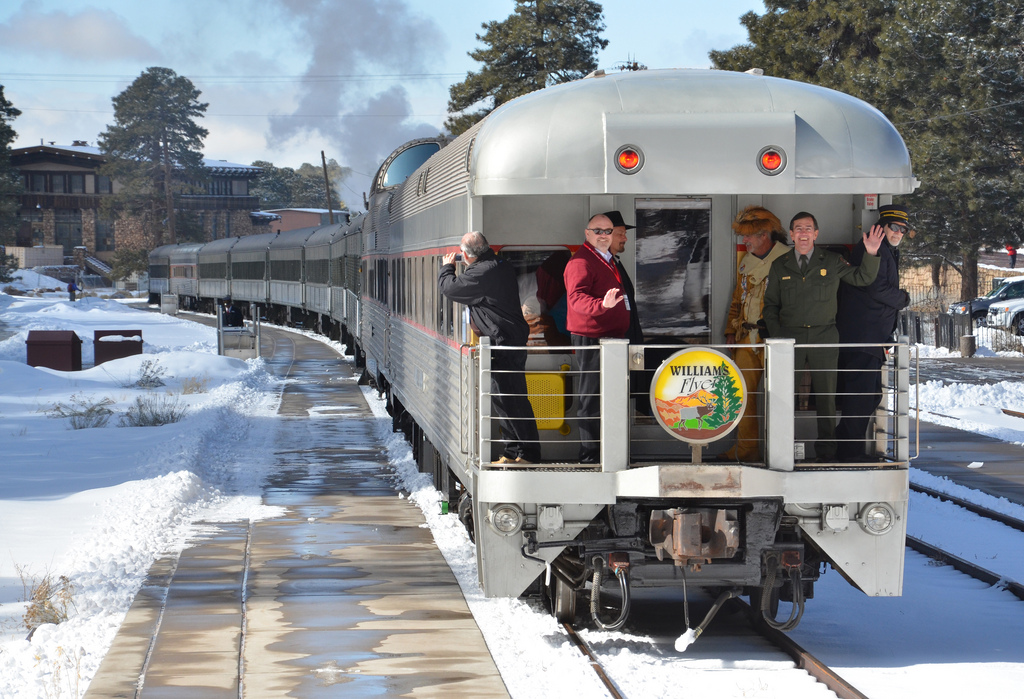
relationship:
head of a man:
[584, 210, 621, 258] [564, 213, 632, 462]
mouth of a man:
[593, 243, 607, 246] [564, 213, 632, 462]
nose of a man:
[597, 230, 610, 246] [564, 213, 632, 462]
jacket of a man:
[564, 240, 632, 338] [564, 213, 632, 462]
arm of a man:
[560, 253, 625, 320] [558, 206, 628, 431]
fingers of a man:
[608, 279, 632, 308] [564, 202, 642, 447]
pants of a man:
[558, 340, 621, 462] [560, 206, 640, 455]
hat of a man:
[606, 212, 637, 232] [603, 204, 640, 339]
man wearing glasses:
[560, 206, 640, 455] [592, 223, 618, 239]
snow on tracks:
[513, 575, 971, 682] [580, 605, 842, 683]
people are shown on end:
[431, 208, 922, 448] [458, 68, 925, 645]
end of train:
[458, 68, 925, 645] [139, 65, 928, 630]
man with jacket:
[754, 206, 889, 455] [752, 251, 886, 351]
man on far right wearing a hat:
[839, 195, 919, 444] [880, 206, 915, 232]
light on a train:
[605, 141, 649, 178] [139, 65, 928, 630]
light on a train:
[754, 137, 794, 179] [139, 65, 928, 630]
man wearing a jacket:
[564, 213, 632, 462] [560, 247, 628, 334]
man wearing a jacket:
[742, 212, 892, 442] [759, 255, 880, 357]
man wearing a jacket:
[839, 195, 919, 444] [848, 253, 913, 334]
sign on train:
[644, 342, 748, 448] [139, 65, 928, 630]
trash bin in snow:
[20, 320, 90, 379] [24, 273, 986, 658]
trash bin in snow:
[89, 323, 150, 371] [24, 273, 986, 658]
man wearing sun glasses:
[564, 213, 632, 462] [584, 215, 624, 239]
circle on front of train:
[644, 342, 751, 448] [139, 65, 928, 630]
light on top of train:
[614, 143, 646, 175] [139, 65, 928, 630]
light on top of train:
[755, 145, 787, 177] [139, 65, 928, 630]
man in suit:
[722, 197, 917, 442] [783, 240, 881, 351]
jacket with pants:
[542, 251, 689, 373] [533, 312, 655, 434]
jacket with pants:
[432, 240, 541, 347] [453, 365, 572, 497]